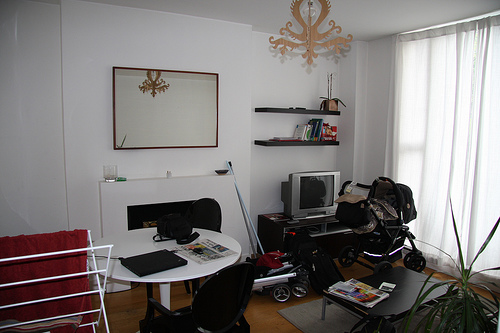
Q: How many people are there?
A: None.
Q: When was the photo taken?
A: Daytime.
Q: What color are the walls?
A: White.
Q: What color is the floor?
A: Brown.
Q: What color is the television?
A: Black and silver.